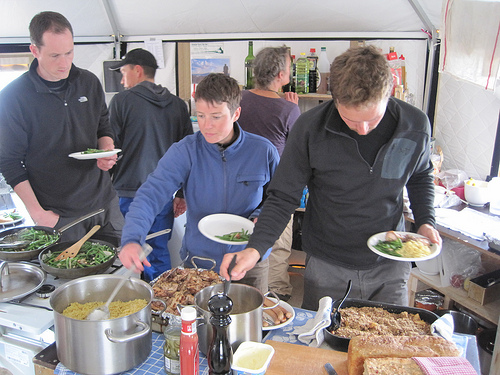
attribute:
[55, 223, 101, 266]
utensil — wooden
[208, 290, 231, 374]
grinder — black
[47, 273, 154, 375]
pot — silver, large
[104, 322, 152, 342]
handle — silver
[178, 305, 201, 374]
bottle — plastic, red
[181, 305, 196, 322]
lid — white, stainless, steal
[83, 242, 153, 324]
spoon — metal, silver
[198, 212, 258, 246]
plate — white, round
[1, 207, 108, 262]
pan — dark, grey, black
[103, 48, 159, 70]
cap — black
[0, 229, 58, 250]
beans — cooked, green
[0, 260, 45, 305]
lid — silver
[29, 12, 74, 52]
hair — short, brown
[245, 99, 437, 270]
sweater — black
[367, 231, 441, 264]
plate — white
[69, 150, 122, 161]
plate — white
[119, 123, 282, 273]
sweater — blue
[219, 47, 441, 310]
person — standing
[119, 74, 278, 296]
person — standing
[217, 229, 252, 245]
beans — green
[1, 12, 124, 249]
person — standing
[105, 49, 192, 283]
person — standing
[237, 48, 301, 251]
person — standing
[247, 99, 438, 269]
shirt — grey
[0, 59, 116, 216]
shirt — grey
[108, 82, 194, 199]
shirt — grey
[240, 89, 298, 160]
shirt — grey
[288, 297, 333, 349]
towel — leaning, white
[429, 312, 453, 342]
towel — leaning, white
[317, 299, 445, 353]
pan — black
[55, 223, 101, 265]
spoon — wooden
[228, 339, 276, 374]
container — plastic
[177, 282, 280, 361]
pot — silver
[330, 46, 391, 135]
head — down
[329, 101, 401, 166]
shirt — black